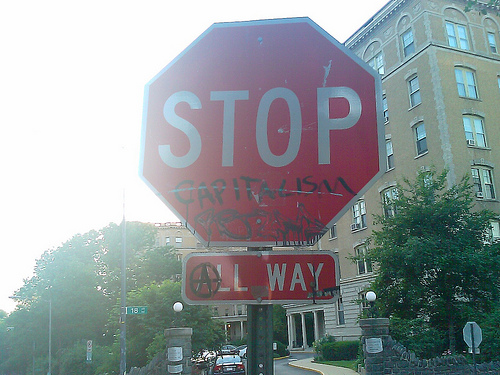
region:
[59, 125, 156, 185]
sunlight reflecting on the sign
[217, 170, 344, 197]
black graffiti on red sign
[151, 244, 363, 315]
small red and white sign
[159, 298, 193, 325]
white light on top of post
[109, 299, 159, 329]
green and white street sign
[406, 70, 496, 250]
brown tall apartment building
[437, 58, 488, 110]
windows in building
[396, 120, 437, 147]
white blinds in window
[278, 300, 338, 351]
large white columns in front of building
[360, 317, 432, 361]
tall gray fence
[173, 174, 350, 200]
spraypaint on a stop sign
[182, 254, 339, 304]
a spraypainted stop sign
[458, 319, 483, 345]
the back of a stop sign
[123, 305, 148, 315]
a green street sign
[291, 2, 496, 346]
a large beige building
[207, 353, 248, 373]
a parked black sedan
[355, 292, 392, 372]
a lamp upon a wooden pillar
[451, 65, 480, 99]
a window in a building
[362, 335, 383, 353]
a sign under a lamp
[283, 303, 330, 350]
a circular entry to a building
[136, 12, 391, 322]
a stop sign on a pole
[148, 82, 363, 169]
words that say Stop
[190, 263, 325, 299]
words that say All Way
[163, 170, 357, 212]
Word that says Capitalism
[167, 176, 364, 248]
grafitti on a sign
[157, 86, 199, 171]
white letter S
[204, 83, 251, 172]
a white letter T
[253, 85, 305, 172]
a white letter O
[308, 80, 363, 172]
a white letter P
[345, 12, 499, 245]
a large building in the distance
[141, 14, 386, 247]
large red and white stop sign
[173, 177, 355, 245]
black graffiti on red and white STOP sign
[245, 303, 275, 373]
green and metal pole holding STOP sign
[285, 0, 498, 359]
large and tan building behind STOP sign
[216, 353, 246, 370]
car parked at large building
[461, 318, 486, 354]
back of STOP sign across the street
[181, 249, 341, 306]
ALL WAY sign with black graffiti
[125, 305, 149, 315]
green and white street sign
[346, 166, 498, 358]
brown tree with green leaves across street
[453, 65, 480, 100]
glass window on building across street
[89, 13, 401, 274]
a red STOP sign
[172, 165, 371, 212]
capitalism written on the sign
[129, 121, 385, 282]
capitalism written on the sign